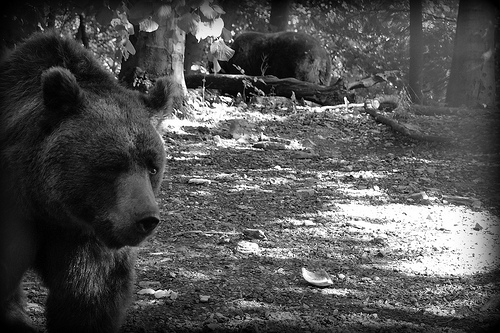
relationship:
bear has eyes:
[12, 22, 187, 291] [108, 153, 165, 180]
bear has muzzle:
[12, 22, 187, 291] [110, 179, 161, 248]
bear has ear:
[12, 22, 187, 291] [31, 60, 99, 114]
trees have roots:
[143, 11, 195, 81] [190, 110, 220, 136]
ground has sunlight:
[240, 113, 347, 210] [371, 194, 458, 268]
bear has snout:
[12, 22, 187, 291] [116, 214, 160, 250]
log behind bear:
[218, 71, 343, 112] [12, 22, 187, 291]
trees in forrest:
[143, 11, 195, 81] [106, 10, 481, 309]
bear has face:
[12, 22, 187, 291] [49, 60, 207, 268]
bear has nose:
[12, 22, 187, 291] [134, 207, 153, 227]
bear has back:
[12, 22, 187, 291] [29, 22, 74, 56]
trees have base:
[143, 11, 195, 81] [162, 88, 200, 119]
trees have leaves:
[143, 11, 195, 81] [204, 110, 227, 136]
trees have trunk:
[143, 11, 195, 81] [397, 36, 433, 74]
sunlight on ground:
[371, 194, 458, 268] [240, 113, 347, 210]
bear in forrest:
[12, 22, 187, 291] [106, 10, 481, 309]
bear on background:
[12, 22, 187, 291] [181, 34, 301, 72]